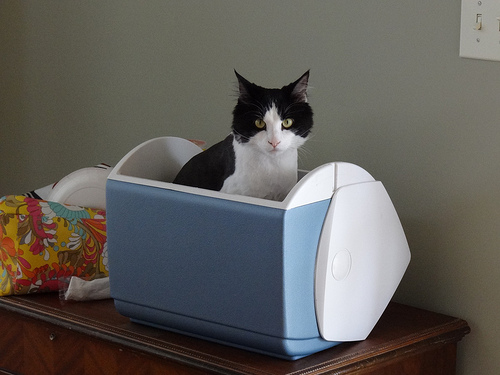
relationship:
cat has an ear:
[173, 68, 314, 201] [285, 69, 311, 105]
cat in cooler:
[173, 68, 314, 201] [106, 136, 412, 361]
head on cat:
[232, 69, 314, 154] [173, 68, 314, 201]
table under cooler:
[0, 292, 470, 373] [106, 136, 412, 361]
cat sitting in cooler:
[173, 68, 314, 201] [106, 136, 412, 361]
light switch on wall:
[474, 14, 483, 31] [0, 0, 499, 373]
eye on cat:
[281, 118, 293, 128] [173, 68, 314, 201]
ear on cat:
[285, 69, 311, 105] [173, 68, 314, 201]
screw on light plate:
[477, 0, 483, 8] [458, 0, 499, 61]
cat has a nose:
[173, 68, 314, 201] [269, 137, 282, 148]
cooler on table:
[106, 136, 412, 361] [0, 292, 470, 373]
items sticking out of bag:
[20, 163, 116, 210] [0, 195, 108, 295]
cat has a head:
[173, 68, 314, 201] [232, 69, 314, 154]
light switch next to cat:
[474, 14, 483, 31] [173, 68, 314, 201]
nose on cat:
[269, 137, 282, 148] [173, 68, 314, 201]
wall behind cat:
[0, 0, 499, 373] [173, 68, 314, 201]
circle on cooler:
[332, 249, 352, 281] [106, 136, 412, 361]